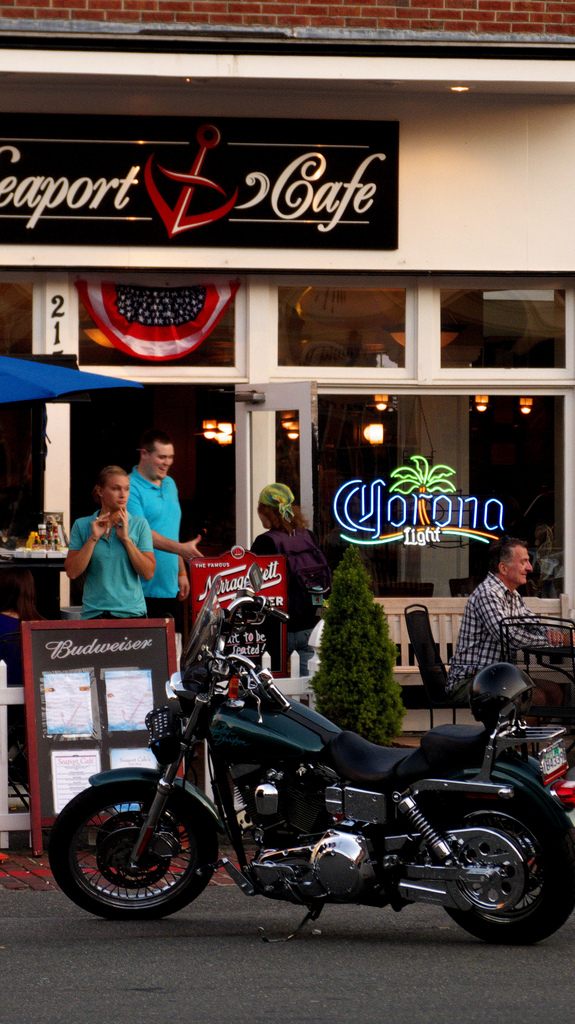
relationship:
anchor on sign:
[134, 120, 239, 239] [0, 110, 397, 248]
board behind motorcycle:
[19, 614, 186, 853] [36, 520, 571, 962]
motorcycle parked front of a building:
[41, 582, 569, 947] [1, 0, 575, 735]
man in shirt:
[448, 540, 572, 728] [445, 571, 567, 686]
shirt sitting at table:
[445, 571, 567, 686] [501, 609, 571, 699]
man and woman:
[122, 431, 210, 615] [65, 462, 153, 617]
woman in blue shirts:
[65, 462, 153, 617] [63, 462, 185, 622]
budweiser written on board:
[42, 632, 157, 659] [19, 615, 186, 855]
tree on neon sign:
[382, 451, 455, 530] [330, 450, 514, 553]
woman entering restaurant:
[247, 483, 325, 667] [1, 110, 405, 252]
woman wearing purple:
[247, 483, 325, 667] [254, 522, 328, 629]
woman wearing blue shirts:
[65, 461, 157, 617] [63, 499, 154, 622]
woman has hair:
[65, 461, 157, 617] [91, 464, 127, 504]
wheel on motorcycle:
[46, 755, 240, 962] [32, 686, 561, 996]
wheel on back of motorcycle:
[428, 778, 575, 949] [41, 582, 569, 947]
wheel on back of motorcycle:
[428, 778, 569, 948] [41, 582, 569, 947]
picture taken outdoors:
[8, 6, 573, 1020] [35, 387, 571, 839]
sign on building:
[0, 110, 397, 248] [1, 0, 573, 650]